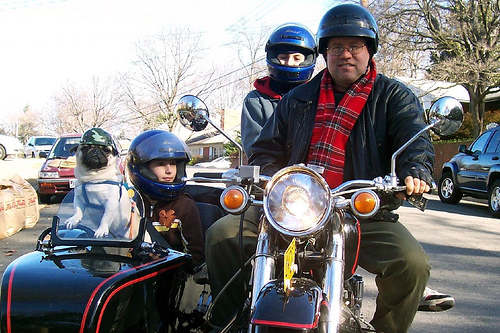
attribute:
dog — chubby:
[63, 127, 140, 240]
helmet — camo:
[77, 129, 116, 149]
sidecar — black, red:
[2, 241, 192, 333]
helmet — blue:
[127, 128, 191, 199]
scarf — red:
[304, 59, 377, 189]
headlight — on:
[262, 164, 333, 237]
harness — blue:
[80, 180, 126, 211]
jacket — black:
[247, 71, 438, 221]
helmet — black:
[316, 2, 380, 53]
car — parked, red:
[33, 136, 128, 197]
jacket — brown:
[140, 196, 204, 271]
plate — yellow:
[283, 238, 297, 290]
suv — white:
[0, 134, 25, 161]